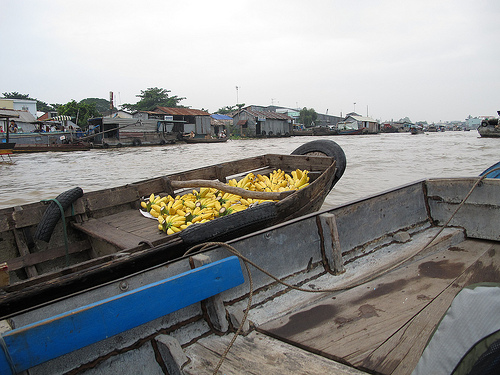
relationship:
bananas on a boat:
[141, 165, 315, 246] [1, 151, 349, 329]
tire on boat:
[290, 135, 346, 184] [1, 151, 349, 329]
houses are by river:
[8, 107, 291, 147] [13, 129, 487, 178]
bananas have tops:
[141, 165, 315, 246] [218, 206, 236, 217]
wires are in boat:
[201, 237, 285, 289] [155, 173, 496, 373]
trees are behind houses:
[54, 83, 205, 116] [8, 107, 291, 147]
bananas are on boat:
[141, 165, 315, 246] [1, 151, 349, 329]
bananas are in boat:
[141, 165, 315, 246] [1, 151, 349, 329]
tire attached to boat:
[290, 135, 346, 184] [1, 151, 349, 329]